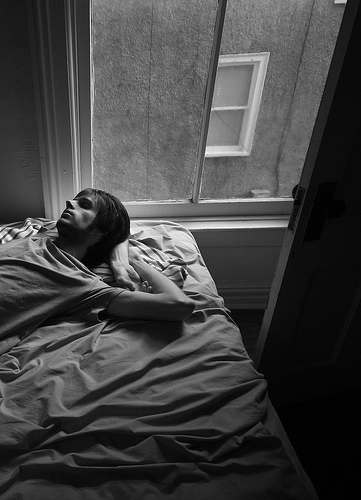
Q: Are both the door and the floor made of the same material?
A: Yes, both the door and the floor are made of wood.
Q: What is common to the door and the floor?
A: The material, both the door and the floor are wooden.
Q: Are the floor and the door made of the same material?
A: Yes, both the floor and the door are made of wood.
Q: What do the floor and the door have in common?
A: The material, both the floor and the door are wooden.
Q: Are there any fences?
A: No, there are no fences.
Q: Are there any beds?
A: Yes, there is a bed.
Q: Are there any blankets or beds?
A: Yes, there is a bed.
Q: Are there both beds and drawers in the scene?
A: No, there is a bed but no drawers.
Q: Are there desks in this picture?
A: No, there are no desks.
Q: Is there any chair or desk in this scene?
A: No, there are no desks or chairs.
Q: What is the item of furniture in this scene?
A: The piece of furniture is a bed.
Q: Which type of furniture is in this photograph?
A: The furniture is a bed.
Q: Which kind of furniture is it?
A: The piece of furniture is a bed.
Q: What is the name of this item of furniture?
A: That is a bed.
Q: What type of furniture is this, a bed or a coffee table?
A: That is a bed.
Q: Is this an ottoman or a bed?
A: This is a bed.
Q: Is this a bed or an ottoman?
A: This is a bed.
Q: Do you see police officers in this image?
A: No, there are no police officers.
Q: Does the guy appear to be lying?
A: Yes, the guy is lying.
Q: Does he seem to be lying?
A: Yes, the guy is lying.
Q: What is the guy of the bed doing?
A: The guy is lying.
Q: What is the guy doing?
A: The guy is lying.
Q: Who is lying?
A: The guy is lying.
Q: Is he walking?
A: No, the guy is lying.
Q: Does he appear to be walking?
A: No, the guy is lying.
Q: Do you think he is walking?
A: No, the guy is lying.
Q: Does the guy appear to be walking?
A: No, the guy is lying.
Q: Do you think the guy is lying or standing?
A: The guy is lying.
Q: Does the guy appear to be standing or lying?
A: The guy is lying.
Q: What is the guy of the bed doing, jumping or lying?
A: The guy is lying.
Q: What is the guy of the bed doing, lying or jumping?
A: The guy is lying.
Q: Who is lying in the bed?
A: The guy is lying in the bed.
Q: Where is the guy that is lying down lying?
A: The guy is lying in the bed.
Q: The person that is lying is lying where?
A: The guy is lying in the bed.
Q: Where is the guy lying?
A: The guy is lying in the bed.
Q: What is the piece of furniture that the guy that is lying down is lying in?
A: The piece of furniture is a bed.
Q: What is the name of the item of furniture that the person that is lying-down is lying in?
A: The piece of furniture is a bed.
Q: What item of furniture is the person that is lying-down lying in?
A: The guy is lying in the bed.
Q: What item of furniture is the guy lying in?
A: The guy is lying in the bed.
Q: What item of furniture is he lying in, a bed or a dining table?
A: The guy is lying in a bed.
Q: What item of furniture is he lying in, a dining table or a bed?
A: The guy is lying in a bed.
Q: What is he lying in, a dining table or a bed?
A: The guy is lying in a bed.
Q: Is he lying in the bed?
A: Yes, the guy is lying in the bed.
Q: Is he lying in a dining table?
A: No, the guy is lying in the bed.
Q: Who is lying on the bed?
A: The guy is lying on the bed.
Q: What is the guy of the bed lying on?
A: The guy is lying on the bed.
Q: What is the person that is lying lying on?
A: The guy is lying on the bed.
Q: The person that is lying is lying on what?
A: The guy is lying on the bed.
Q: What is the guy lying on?
A: The guy is lying on the bed.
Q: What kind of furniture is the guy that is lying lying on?
A: The guy is lying on the bed.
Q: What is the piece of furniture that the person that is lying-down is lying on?
A: The piece of furniture is a bed.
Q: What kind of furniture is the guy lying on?
A: The guy is lying on the bed.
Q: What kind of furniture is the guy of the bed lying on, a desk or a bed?
A: The guy is lying on a bed.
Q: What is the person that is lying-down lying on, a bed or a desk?
A: The guy is lying on a bed.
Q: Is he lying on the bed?
A: Yes, the guy is lying on the bed.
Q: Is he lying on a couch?
A: No, the guy is lying on the bed.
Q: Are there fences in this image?
A: No, there are no fences.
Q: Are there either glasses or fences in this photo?
A: No, there are no fences or glasses.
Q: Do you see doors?
A: Yes, there is a door.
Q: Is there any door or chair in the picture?
A: Yes, there is a door.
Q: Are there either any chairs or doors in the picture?
A: Yes, there is a door.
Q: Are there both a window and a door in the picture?
A: Yes, there are both a door and a window.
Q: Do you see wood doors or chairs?
A: Yes, there is a wood door.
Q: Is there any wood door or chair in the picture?
A: Yes, there is a wood door.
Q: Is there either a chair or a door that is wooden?
A: Yes, the door is wooden.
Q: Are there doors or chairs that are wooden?
A: Yes, the door is wooden.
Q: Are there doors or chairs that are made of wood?
A: Yes, the door is made of wood.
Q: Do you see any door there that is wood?
A: Yes, there is a wood door.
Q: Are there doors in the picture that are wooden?
A: Yes, there is a door that is wooden.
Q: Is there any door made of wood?
A: Yes, there is a door that is made of wood.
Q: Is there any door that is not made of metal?
A: Yes, there is a door that is made of wood.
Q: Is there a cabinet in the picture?
A: No, there are no cabinets.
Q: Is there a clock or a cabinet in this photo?
A: No, there are no cabinets or clocks.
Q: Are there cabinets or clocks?
A: No, there are no cabinets or clocks.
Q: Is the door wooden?
A: Yes, the door is wooden.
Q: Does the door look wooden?
A: Yes, the door is wooden.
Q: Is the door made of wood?
A: Yes, the door is made of wood.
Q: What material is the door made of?
A: The door is made of wood.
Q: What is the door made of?
A: The door is made of wood.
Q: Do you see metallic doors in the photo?
A: No, there is a door but it is wooden.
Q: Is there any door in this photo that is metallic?
A: No, there is a door but it is wooden.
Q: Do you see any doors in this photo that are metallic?
A: No, there is a door but it is wooden.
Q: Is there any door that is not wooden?
A: No, there is a door but it is wooden.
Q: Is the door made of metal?
A: No, the door is made of wood.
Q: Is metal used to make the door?
A: No, the door is made of wood.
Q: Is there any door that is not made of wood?
A: No, there is a door but it is made of wood.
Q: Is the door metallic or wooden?
A: The door is wooden.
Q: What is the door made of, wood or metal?
A: The door is made of wood.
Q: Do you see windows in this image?
A: Yes, there is a window.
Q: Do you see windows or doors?
A: Yes, there is a window.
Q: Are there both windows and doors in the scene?
A: Yes, there are both a window and a door.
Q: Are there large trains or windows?
A: Yes, there is a large window.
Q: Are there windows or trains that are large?
A: Yes, the window is large.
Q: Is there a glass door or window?
A: Yes, there is a glass window.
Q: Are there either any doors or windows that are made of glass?
A: Yes, the window is made of glass.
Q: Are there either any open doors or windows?
A: Yes, there is an open window.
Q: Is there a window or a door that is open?
A: Yes, the window is open.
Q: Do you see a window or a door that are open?
A: Yes, the window is open.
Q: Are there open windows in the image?
A: Yes, there is an open window.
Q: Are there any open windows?
A: Yes, there is an open window.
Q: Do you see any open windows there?
A: Yes, there is an open window.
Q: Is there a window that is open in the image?
A: Yes, there is an open window.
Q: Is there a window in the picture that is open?
A: Yes, there is a window that is open.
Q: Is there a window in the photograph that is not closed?
A: Yes, there is a open window.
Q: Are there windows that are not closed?
A: Yes, there is a open window.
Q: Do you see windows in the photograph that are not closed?
A: Yes, there is a open window.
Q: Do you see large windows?
A: Yes, there is a large window.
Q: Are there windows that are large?
A: Yes, there is a window that is large.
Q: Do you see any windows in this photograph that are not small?
A: Yes, there is a large window.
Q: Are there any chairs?
A: No, there are no chairs.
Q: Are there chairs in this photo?
A: No, there are no chairs.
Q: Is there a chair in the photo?
A: No, there are no chairs.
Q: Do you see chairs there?
A: No, there are no chairs.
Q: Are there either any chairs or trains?
A: No, there are no chairs or trains.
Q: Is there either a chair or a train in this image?
A: No, there are no chairs or trains.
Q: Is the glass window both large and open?
A: Yes, the window is large and open.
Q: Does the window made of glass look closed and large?
A: No, the window is large but open.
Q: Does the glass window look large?
A: Yes, the window is large.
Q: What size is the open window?
A: The window is large.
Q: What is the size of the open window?
A: The window is large.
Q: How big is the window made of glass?
A: The window is large.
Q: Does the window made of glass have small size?
A: No, the window is large.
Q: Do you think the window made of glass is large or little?
A: The window is large.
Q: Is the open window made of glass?
A: Yes, the window is made of glass.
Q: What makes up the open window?
A: The window is made of glass.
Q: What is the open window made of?
A: The window is made of glass.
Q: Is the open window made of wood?
A: No, the window is made of glass.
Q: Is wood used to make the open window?
A: No, the window is made of glass.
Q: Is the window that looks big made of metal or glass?
A: The window is made of glass.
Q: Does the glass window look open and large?
A: Yes, the window is open and large.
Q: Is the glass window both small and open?
A: No, the window is open but large.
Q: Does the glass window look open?
A: Yes, the window is open.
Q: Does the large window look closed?
A: No, the window is open.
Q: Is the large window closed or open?
A: The window is open.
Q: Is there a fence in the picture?
A: No, there are no fences.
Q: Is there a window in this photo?
A: Yes, there is a window.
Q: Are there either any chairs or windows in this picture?
A: Yes, there is a window.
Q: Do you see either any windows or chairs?
A: Yes, there is a window.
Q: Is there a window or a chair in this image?
A: Yes, there is a window.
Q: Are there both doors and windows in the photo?
A: Yes, there are both a window and doors.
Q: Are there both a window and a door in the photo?
A: Yes, there are both a window and a door.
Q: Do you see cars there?
A: No, there are no cars.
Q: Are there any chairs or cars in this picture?
A: No, there are no cars or chairs.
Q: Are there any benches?
A: No, there are no benches.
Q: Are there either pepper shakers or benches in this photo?
A: No, there are no benches or pepper shakers.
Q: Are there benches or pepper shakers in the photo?
A: No, there are no benches or pepper shakers.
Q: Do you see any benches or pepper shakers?
A: No, there are no benches or pepper shakers.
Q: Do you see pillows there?
A: No, there are no pillows.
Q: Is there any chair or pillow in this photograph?
A: No, there are no pillows or chairs.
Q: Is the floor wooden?
A: Yes, the floor is wooden.